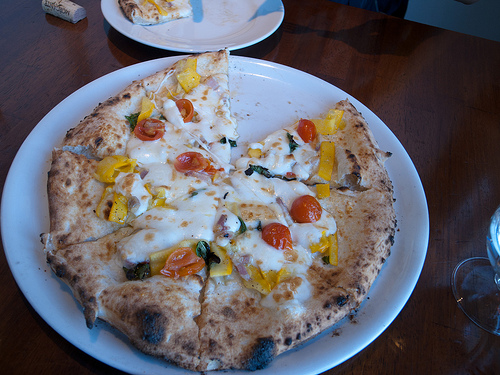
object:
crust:
[196, 281, 351, 375]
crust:
[325, 97, 393, 197]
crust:
[45, 152, 127, 244]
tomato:
[290, 194, 323, 223]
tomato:
[261, 221, 296, 252]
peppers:
[91, 155, 140, 182]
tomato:
[175, 98, 196, 124]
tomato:
[173, 149, 208, 176]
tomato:
[161, 243, 204, 280]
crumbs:
[254, 101, 261, 108]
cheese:
[235, 151, 300, 202]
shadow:
[286, 8, 434, 59]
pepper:
[317, 141, 336, 182]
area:
[236, 334, 282, 370]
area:
[136, 302, 171, 345]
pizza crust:
[324, 189, 398, 288]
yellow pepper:
[174, 57, 203, 91]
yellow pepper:
[133, 96, 156, 122]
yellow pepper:
[94, 154, 138, 184]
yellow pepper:
[95, 187, 128, 225]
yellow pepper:
[144, 184, 174, 209]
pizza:
[38, 47, 400, 374]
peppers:
[312, 110, 352, 136]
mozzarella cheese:
[145, 212, 200, 252]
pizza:
[50, 189, 218, 369]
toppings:
[310, 229, 339, 266]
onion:
[276, 196, 295, 228]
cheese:
[212, 178, 269, 203]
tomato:
[132, 116, 167, 141]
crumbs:
[287, 100, 292, 105]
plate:
[0, 50, 430, 375]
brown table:
[0, 9, 500, 375]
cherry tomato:
[296, 118, 317, 145]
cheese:
[123, 194, 226, 262]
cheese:
[123, 114, 208, 166]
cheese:
[238, 127, 321, 178]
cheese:
[162, 73, 236, 172]